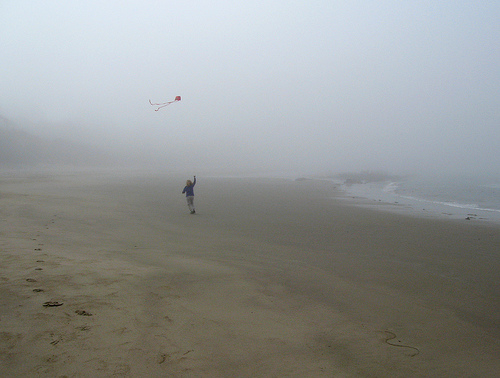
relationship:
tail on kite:
[148, 94, 175, 113] [146, 90, 193, 125]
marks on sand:
[23, 234, 98, 342] [0, 164, 497, 374]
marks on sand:
[147, 307, 202, 370] [0, 164, 497, 374]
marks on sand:
[370, 319, 428, 364] [0, 164, 497, 374]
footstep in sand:
[35, 245, 44, 255] [0, 164, 497, 374]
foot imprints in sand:
[72, 307, 96, 319] [0, 164, 497, 374]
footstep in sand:
[41, 300, 66, 307] [0, 164, 497, 374]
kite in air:
[147, 91, 183, 114] [71, 35, 450, 215]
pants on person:
[182, 191, 197, 216] [177, 173, 200, 217]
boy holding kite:
[173, 175, 198, 215] [138, 90, 193, 112]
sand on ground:
[0, 164, 497, 374] [14, 179, 483, 376]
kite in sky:
[141, 87, 193, 124] [85, 10, 462, 77]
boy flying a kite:
[182, 175, 198, 214] [148, 91, 182, 126]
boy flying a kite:
[182, 175, 198, 214] [148, 92, 188, 116]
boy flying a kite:
[182, 175, 198, 214] [144, 92, 183, 113]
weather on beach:
[62, 62, 432, 321] [19, 22, 499, 361]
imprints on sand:
[32, 245, 104, 338] [111, 221, 430, 358]